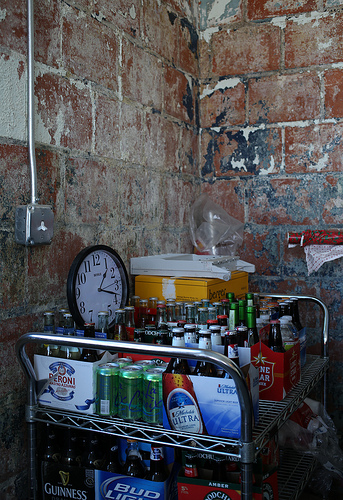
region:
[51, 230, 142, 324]
clock in front of wall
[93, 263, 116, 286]
small hand on the clock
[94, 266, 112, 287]
small hand pointing at 1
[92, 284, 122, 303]
larger hand of clock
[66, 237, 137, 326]
round clock in the photo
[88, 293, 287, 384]
beers in front of clock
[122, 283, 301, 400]
many cases of beer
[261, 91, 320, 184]
wall with many marks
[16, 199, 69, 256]
light on the brick wall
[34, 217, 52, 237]
switch on the light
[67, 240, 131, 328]
A clock near the wall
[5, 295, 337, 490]
Different brands of bear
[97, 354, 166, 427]
Green color cans of bear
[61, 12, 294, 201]
A red brick wall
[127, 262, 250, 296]
A yellow color box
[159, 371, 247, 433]
A picture of bear bottle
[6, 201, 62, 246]
A socket in the wall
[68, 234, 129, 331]
The time of the clock is 1:18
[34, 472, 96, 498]
Guiness bears under the tray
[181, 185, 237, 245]
A plastic cover on the side of the wall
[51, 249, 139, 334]
a clock with a black frame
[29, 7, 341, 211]
parrt of a brick wall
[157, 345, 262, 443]
a case of Michelob beer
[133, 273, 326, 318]
a yellow box on the cart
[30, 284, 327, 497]
a metal cart holding cans and bottles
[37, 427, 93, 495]
a case of Guinness beer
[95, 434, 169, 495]
a case of Bud Light beer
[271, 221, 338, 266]
a roll of wrapping paper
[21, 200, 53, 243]
a light switch on the brick wall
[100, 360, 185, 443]
six cans of La Croix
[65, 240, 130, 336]
A circle shaped clock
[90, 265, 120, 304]
Black hands on the clock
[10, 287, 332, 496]
A silver metal cart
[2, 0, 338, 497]
Dirty bricks on the walls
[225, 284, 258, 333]
Five green colored bottles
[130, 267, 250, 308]
A yellow colored box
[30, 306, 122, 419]
Bottles in a white carton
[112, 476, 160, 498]
The word "BUD" on a carton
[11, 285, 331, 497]
Beer on a metal cart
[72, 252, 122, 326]
Numbers on the clock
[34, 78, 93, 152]
Chipping paint on the bricks.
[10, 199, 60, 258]
Silver light switch on the wall.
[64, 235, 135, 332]
Black and white clock propped on the wall.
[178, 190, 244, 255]
Plastic bag in the corner.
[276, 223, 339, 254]
Red and green umbrella on the side.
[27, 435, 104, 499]
A twelve pack of Guinness.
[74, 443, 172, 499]
Twelve pack of Bud Light..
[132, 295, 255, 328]
Many different bottles of beer.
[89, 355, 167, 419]
Green cans with blue writing.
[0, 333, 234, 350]
Silver handle on the cart.